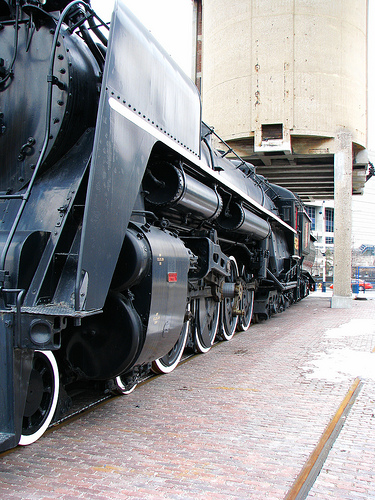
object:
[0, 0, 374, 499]
picture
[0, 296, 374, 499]
ground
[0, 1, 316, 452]
train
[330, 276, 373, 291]
car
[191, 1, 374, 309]
siloh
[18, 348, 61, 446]
wheel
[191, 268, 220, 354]
wheel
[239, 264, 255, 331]
wheel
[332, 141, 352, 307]
pillar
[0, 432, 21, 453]
step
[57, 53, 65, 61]
rivets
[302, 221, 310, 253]
sign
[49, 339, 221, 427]
rail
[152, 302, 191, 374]
wheels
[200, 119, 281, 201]
rail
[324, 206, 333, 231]
windows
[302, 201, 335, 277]
building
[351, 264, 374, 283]
fence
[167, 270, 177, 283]
red spot